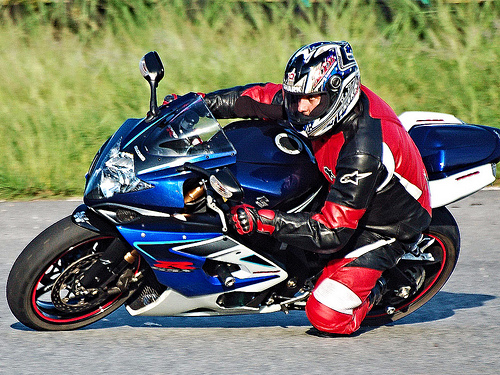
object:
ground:
[3, 0, 498, 373]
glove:
[226, 197, 278, 238]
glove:
[159, 91, 206, 116]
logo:
[152, 261, 192, 271]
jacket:
[203, 82, 432, 255]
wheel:
[350, 205, 461, 327]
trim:
[115, 226, 288, 318]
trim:
[82, 91, 238, 211]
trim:
[409, 122, 499, 181]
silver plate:
[306, 81, 361, 137]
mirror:
[138, 50, 164, 84]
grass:
[0, 1, 499, 201]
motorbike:
[5, 49, 498, 331]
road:
[0, 199, 495, 374]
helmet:
[280, 40, 362, 137]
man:
[163, 40, 434, 336]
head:
[281, 40, 360, 139]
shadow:
[403, 290, 495, 325]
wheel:
[6, 213, 150, 333]